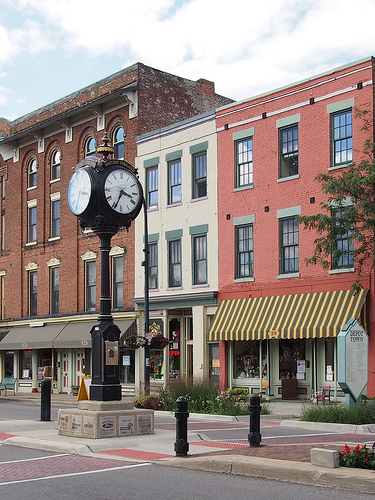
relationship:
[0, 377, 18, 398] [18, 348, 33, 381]
bench in front of window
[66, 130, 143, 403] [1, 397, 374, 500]
clock next to street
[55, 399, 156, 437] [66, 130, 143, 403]
base of clock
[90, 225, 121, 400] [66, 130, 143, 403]
pole of clock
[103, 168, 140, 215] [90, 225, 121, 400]
clock face on pole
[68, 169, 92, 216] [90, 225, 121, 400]
clock face on pole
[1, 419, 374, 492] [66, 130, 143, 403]
pavement near clock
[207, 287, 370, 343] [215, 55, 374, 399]
awning on building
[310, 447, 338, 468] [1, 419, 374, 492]
block on pavement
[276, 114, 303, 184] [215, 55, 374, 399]
window on building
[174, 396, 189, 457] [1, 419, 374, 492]
pole on pavement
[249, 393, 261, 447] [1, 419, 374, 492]
pole on pavement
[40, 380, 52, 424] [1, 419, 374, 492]
pole on pavement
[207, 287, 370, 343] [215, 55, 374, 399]
awning in front of building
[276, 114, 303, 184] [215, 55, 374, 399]
window in front of building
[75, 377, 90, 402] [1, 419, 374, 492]
triangle on pavement